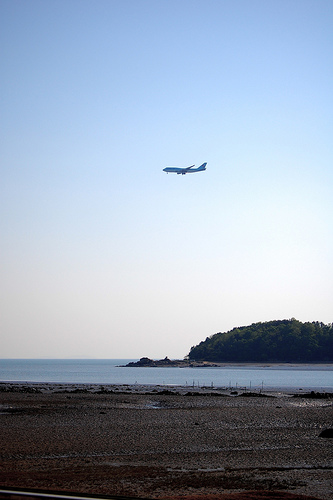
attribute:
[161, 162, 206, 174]
airliner — flying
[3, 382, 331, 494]
beach — dark sandy, rocky, wet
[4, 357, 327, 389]
water — dirty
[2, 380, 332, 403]
sand — brown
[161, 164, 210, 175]
airliner — commercial airliner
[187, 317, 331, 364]
forest — large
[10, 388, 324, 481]
sand — light colored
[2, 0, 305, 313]
sky — blue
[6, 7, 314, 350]
sky — clear, blue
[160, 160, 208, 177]
airplane — commercial airplane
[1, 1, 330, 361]
sky — blue, white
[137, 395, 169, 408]
water puddle — water 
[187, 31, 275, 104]
sky — white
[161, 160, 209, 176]
plane — flying, dark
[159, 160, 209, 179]
plane — large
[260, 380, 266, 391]
twig — large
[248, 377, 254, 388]
twig — large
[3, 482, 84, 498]
line — white line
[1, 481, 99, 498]
surface — paved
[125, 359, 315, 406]
water — inlet of water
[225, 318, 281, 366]
trees — dark green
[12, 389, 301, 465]
beach — brown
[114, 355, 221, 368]
land — point of land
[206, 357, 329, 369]
shoreline — distant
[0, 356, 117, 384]
water — large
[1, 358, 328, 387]
water — blue water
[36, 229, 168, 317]
sky — very light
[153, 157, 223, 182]
airplane — airborne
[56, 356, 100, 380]
water — bright, blue patch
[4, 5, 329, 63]
sky — dark blue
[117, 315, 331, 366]
peninsula — small